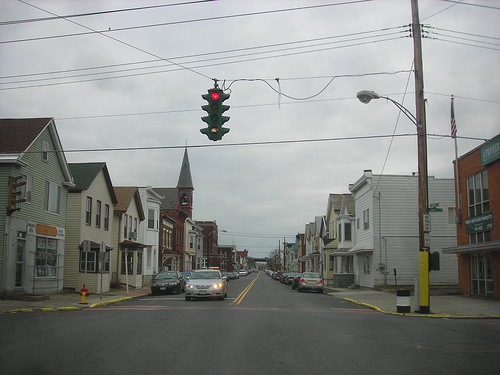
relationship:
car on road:
[182, 263, 230, 301] [33, 253, 489, 374]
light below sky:
[192, 79, 248, 147] [1, 3, 500, 232]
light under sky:
[192, 79, 248, 147] [1, 3, 500, 232]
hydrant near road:
[71, 282, 96, 308] [33, 253, 489, 374]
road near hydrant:
[33, 253, 489, 374] [71, 282, 96, 308]